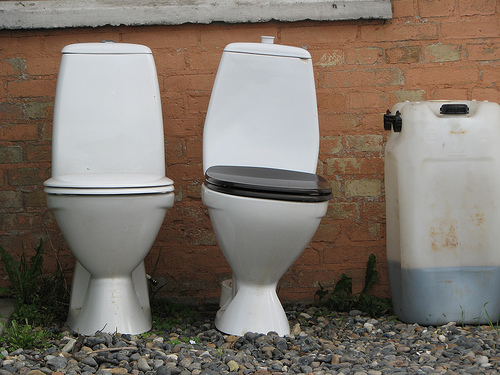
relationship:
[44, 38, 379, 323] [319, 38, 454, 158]
toilets by wall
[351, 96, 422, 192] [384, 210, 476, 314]
knozzle for jug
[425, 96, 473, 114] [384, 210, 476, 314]
cap for jug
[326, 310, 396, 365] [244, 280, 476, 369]
rocks on ground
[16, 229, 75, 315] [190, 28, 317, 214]
weeds by toilet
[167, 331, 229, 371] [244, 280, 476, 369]
gravel on ground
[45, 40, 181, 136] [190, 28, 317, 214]
tank on toilet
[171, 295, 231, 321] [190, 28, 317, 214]
grass by toilet